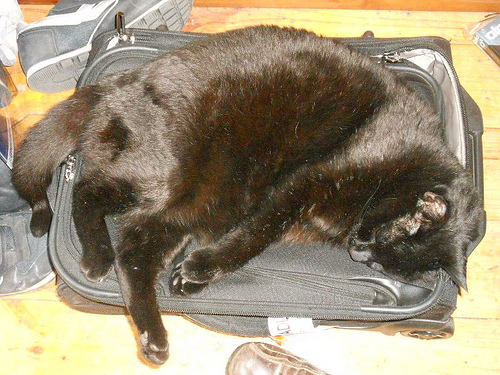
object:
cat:
[10, 24, 479, 365]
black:
[80, 189, 94, 203]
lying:
[8, 23, 483, 364]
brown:
[236, 362, 252, 373]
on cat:
[335, 115, 404, 189]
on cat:
[137, 113, 217, 185]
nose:
[350, 236, 364, 259]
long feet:
[127, 303, 170, 352]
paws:
[78, 254, 116, 284]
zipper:
[65, 155, 73, 181]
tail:
[11, 81, 98, 239]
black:
[271, 288, 281, 296]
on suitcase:
[345, 276, 431, 307]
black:
[68, 30, 75, 36]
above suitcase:
[113, 26, 171, 52]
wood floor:
[362, 13, 449, 34]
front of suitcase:
[181, 298, 329, 340]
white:
[275, 320, 283, 325]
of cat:
[12, 96, 92, 237]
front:
[183, 245, 240, 285]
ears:
[418, 191, 451, 227]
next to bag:
[317, 335, 401, 345]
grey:
[467, 106, 476, 116]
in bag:
[400, 46, 468, 168]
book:
[463, 12, 500, 68]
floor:
[477, 82, 493, 106]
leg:
[102, 199, 171, 364]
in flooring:
[391, 17, 435, 34]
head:
[346, 183, 479, 290]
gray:
[31, 53, 38, 61]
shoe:
[16, 0, 192, 92]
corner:
[461, 24, 471, 34]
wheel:
[399, 315, 453, 339]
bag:
[44, 13, 484, 338]